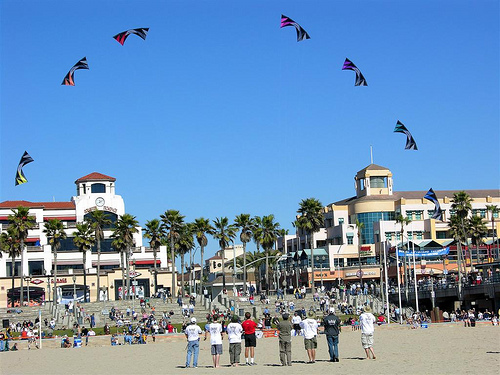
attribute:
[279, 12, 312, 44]
kite — flying, airborn, blue, colorful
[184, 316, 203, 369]
man — light, standing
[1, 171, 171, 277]
building — present, white, blue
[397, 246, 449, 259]
banner — blue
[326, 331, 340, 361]
jeans — blue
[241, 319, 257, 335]
shirt — red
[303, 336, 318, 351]
shorts — green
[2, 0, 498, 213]
sky — cloudless, blue, up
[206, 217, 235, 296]
tree — green, present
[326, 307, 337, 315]
cap — white, present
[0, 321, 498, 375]
beach — present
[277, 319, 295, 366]
outfit — khaki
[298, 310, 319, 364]
person — looking